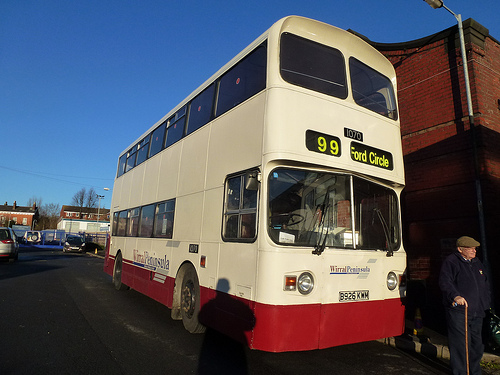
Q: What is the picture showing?
A: It is showing a road.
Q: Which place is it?
A: It is a road.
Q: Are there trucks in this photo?
A: No, there are no trucks.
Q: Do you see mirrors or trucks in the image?
A: No, there are no trucks or mirrors.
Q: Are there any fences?
A: No, there are no fences.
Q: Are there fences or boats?
A: No, there are no fences or boats.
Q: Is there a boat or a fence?
A: No, there are no fences or boats.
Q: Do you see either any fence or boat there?
A: No, there are no fences or boats.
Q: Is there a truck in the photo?
A: No, there are no trucks.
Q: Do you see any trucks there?
A: No, there are no trucks.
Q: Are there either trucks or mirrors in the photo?
A: No, there are no trucks or mirrors.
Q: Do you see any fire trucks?
A: No, there are no fire trucks.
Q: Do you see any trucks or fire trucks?
A: No, there are no fire trucks or trucks.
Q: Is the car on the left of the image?
A: Yes, the car is on the left of the image.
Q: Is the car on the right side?
A: No, the car is on the left of the image.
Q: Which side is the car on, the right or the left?
A: The car is on the left of the image.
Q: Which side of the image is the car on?
A: The car is on the left of the image.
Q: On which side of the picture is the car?
A: The car is on the left of the image.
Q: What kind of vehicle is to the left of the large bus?
A: The vehicle is a car.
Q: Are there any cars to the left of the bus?
A: Yes, there is a car to the left of the bus.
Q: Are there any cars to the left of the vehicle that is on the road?
A: Yes, there is a car to the left of the bus.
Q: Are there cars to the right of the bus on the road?
A: No, the car is to the left of the bus.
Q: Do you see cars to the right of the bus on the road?
A: No, the car is to the left of the bus.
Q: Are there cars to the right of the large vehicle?
A: No, the car is to the left of the bus.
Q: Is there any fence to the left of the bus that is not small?
A: No, there is a car to the left of the bus.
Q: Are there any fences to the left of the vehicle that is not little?
A: No, there is a car to the left of the bus.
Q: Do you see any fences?
A: No, there are no fences.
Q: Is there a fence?
A: No, there are no fences.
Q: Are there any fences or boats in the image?
A: No, there are no fences or boats.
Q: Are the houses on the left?
A: Yes, the houses are on the left of the image.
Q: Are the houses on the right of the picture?
A: No, the houses are on the left of the image.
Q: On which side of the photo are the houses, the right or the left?
A: The houses are on the left of the image.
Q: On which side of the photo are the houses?
A: The houses are on the left of the image.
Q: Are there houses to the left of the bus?
A: Yes, there are houses to the left of the bus.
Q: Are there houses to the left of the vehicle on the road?
A: Yes, there are houses to the left of the bus.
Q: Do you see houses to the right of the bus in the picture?
A: No, the houses are to the left of the bus.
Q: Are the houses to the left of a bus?
A: Yes, the houses are to the left of a bus.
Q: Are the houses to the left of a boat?
A: No, the houses are to the left of a bus.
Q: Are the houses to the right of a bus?
A: No, the houses are to the left of a bus.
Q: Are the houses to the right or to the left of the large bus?
A: The houses are to the left of the bus.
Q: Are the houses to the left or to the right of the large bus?
A: The houses are to the left of the bus.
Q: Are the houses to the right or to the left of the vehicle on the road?
A: The houses are to the left of the bus.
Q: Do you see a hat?
A: Yes, there is a hat.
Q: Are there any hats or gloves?
A: Yes, there is a hat.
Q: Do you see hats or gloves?
A: Yes, there is a hat.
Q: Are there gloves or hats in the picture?
A: Yes, there is a hat.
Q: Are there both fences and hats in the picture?
A: No, there is a hat but no fences.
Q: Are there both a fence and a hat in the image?
A: No, there is a hat but no fences.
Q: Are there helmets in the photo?
A: No, there are no helmets.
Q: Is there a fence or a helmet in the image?
A: No, there are no helmets or fences.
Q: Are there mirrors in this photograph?
A: No, there are no mirrors.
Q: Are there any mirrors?
A: No, there are no mirrors.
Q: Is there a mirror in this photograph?
A: No, there are no mirrors.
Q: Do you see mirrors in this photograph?
A: No, there are no mirrors.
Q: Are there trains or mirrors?
A: No, there are no mirrors or trains.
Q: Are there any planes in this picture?
A: No, there are no planes.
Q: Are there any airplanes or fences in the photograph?
A: No, there are no airplanes or fences.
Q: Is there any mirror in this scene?
A: No, there are no mirrors.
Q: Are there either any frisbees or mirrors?
A: No, there are no mirrors or frisbees.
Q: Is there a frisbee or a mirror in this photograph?
A: No, there are no mirrors or frisbees.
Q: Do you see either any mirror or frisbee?
A: No, there are no mirrors or frisbees.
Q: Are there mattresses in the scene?
A: No, there are no mattresses.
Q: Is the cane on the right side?
A: Yes, the cane is on the right of the image.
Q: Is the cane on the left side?
A: No, the cane is on the right of the image.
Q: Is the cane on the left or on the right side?
A: The cane is on the right of the image.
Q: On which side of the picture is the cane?
A: The cane is on the right of the image.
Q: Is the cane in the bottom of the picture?
A: Yes, the cane is in the bottom of the image.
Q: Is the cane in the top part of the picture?
A: No, the cane is in the bottom of the image.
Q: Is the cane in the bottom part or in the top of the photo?
A: The cane is in the bottom of the image.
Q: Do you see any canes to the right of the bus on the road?
A: Yes, there is a cane to the right of the bus.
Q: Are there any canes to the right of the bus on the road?
A: Yes, there is a cane to the right of the bus.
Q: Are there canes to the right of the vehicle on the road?
A: Yes, there is a cane to the right of the bus.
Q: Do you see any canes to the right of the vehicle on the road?
A: Yes, there is a cane to the right of the bus.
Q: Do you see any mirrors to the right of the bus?
A: No, there is a cane to the right of the bus.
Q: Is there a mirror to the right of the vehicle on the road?
A: No, there is a cane to the right of the bus.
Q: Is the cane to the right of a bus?
A: Yes, the cane is to the right of a bus.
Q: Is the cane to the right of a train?
A: No, the cane is to the right of a bus.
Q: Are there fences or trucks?
A: No, there are no fences or trucks.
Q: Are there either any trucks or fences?
A: No, there are no fences or trucks.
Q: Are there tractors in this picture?
A: No, there are no tractors.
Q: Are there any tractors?
A: No, there are no tractors.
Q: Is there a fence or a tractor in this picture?
A: No, there are no tractors or fences.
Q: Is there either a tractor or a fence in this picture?
A: No, there are no tractors or fences.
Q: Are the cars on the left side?
A: Yes, the cars are on the left of the image.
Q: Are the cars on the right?
A: No, the cars are on the left of the image.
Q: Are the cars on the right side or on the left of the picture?
A: The cars are on the left of the image.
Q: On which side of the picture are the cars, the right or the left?
A: The cars are on the left of the image.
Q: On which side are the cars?
A: The cars are on the left of the image.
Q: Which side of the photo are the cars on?
A: The cars are on the left of the image.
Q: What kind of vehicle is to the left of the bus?
A: The vehicles are cars.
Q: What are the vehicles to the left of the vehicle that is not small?
A: The vehicles are cars.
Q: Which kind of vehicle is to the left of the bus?
A: The vehicles are cars.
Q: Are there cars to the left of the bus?
A: Yes, there are cars to the left of the bus.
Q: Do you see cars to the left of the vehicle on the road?
A: Yes, there are cars to the left of the bus.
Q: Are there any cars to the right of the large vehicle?
A: No, the cars are to the left of the bus.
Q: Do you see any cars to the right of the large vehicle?
A: No, the cars are to the left of the bus.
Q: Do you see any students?
A: No, there are no students.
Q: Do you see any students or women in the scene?
A: No, there are no students or women.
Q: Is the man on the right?
A: Yes, the man is on the right of the image.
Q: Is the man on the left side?
A: No, the man is on the right of the image.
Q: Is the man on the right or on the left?
A: The man is on the right of the image.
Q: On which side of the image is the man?
A: The man is on the right of the image.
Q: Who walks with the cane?
A: The man walks with the cane.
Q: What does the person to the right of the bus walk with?
A: The man walks with a cane.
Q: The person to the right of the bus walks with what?
A: The man walks with a cane.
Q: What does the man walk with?
A: The man walks with a cane.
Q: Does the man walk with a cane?
A: Yes, the man walks with a cane.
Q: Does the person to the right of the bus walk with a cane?
A: Yes, the man walks with a cane.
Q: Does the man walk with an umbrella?
A: No, the man walks with a cane.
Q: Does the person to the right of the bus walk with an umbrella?
A: No, the man walks with a cane.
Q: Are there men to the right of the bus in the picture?
A: Yes, there is a man to the right of the bus.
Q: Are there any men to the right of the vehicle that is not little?
A: Yes, there is a man to the right of the bus.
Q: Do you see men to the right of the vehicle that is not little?
A: Yes, there is a man to the right of the bus.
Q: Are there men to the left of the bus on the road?
A: No, the man is to the right of the bus.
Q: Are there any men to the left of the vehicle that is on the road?
A: No, the man is to the right of the bus.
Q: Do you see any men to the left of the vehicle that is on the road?
A: No, the man is to the right of the bus.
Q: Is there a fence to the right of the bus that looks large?
A: No, there is a man to the right of the bus.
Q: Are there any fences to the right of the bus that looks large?
A: No, there is a man to the right of the bus.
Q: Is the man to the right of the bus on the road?
A: Yes, the man is to the right of the bus.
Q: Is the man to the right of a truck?
A: No, the man is to the right of the bus.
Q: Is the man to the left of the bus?
A: No, the man is to the right of the bus.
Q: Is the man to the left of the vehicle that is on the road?
A: No, the man is to the right of the bus.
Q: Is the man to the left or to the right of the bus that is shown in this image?
A: The man is to the right of the bus.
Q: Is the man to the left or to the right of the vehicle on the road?
A: The man is to the right of the bus.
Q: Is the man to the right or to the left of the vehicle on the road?
A: The man is to the right of the bus.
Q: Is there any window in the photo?
A: Yes, there are windows.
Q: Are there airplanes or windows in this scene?
A: Yes, there are windows.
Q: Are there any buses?
A: Yes, there is a bus.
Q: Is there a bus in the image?
A: Yes, there is a bus.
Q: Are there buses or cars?
A: Yes, there is a bus.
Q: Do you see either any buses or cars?
A: Yes, there is a bus.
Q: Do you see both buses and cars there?
A: Yes, there are both a bus and a car.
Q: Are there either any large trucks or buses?
A: Yes, there is a large bus.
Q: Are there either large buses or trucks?
A: Yes, there is a large bus.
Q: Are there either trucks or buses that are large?
A: Yes, the bus is large.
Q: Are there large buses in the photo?
A: Yes, there is a large bus.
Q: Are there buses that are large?
A: Yes, there is a bus that is large.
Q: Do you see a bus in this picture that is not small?
A: Yes, there is a large bus.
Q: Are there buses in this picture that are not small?
A: Yes, there is a large bus.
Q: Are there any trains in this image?
A: No, there are no trains.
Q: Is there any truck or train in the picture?
A: No, there are no trains or trucks.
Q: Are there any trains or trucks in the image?
A: No, there are no trains or trucks.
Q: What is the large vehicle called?
A: The vehicle is a bus.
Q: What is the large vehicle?
A: The vehicle is a bus.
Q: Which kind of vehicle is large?
A: The vehicle is a bus.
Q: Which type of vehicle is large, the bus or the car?
A: The bus is large.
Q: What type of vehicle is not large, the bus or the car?
A: The car is not large.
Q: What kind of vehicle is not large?
A: The vehicle is a car.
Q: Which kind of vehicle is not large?
A: The vehicle is a car.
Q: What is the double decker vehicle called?
A: The vehicle is a bus.